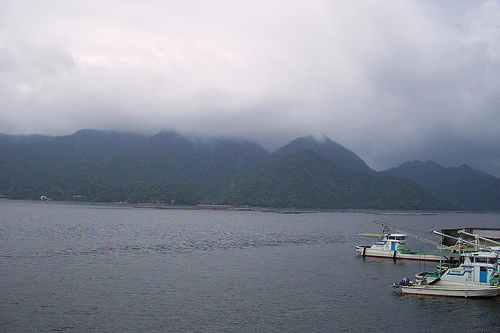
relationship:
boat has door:
[379, 245, 497, 311] [476, 260, 493, 287]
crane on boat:
[379, 219, 460, 255] [352, 219, 475, 266]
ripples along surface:
[167, 216, 337, 261] [4, 200, 452, 324]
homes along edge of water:
[5, 192, 229, 207] [3, 211, 498, 331]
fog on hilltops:
[18, 3, 498, 163] [1, 95, 428, 185]